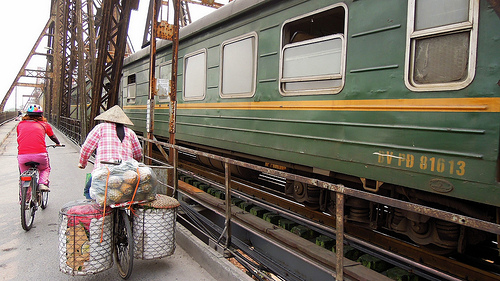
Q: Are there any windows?
A: Yes, there is a window.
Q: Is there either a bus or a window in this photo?
A: Yes, there is a window.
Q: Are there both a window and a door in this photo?
A: No, there is a window but no doors.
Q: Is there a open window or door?
A: Yes, there is an open window.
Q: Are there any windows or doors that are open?
A: Yes, the window is open.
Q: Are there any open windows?
A: Yes, there is an open window.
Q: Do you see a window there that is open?
A: Yes, there is a window that is open.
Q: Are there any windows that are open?
A: Yes, there is a window that is open.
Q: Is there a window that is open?
A: Yes, there is a window that is open.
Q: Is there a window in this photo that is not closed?
A: Yes, there is a open window.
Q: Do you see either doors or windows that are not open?
A: No, there is a window but it is open.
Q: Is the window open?
A: Yes, the window is open.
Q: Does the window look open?
A: Yes, the window is open.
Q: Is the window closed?
A: No, the window is open.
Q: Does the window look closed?
A: No, the window is open.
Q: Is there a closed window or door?
A: No, there is a window but it is open.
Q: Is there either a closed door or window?
A: No, there is a window but it is open.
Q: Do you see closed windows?
A: No, there is a window but it is open.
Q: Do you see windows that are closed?
A: No, there is a window but it is open.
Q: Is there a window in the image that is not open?
A: No, there is a window but it is open.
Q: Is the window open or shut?
A: The window is open.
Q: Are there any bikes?
A: Yes, there is a bike.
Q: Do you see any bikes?
A: Yes, there is a bike.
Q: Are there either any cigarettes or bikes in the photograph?
A: Yes, there is a bike.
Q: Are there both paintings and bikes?
A: No, there is a bike but no paintings.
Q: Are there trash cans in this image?
A: No, there are no trash cans.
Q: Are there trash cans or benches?
A: No, there are no trash cans or benches.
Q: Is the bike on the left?
A: Yes, the bike is on the left of the image.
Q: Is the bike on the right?
A: No, the bike is on the left of the image.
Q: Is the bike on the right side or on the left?
A: The bike is on the left of the image.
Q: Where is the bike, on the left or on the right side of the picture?
A: The bike is on the left of the image.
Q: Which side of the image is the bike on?
A: The bike is on the left of the image.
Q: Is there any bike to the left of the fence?
A: Yes, there is a bike to the left of the fence.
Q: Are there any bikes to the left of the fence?
A: Yes, there is a bike to the left of the fence.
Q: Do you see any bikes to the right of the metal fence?
A: No, the bike is to the left of the fence.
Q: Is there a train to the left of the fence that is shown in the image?
A: No, there is a bike to the left of the fence.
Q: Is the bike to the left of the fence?
A: Yes, the bike is to the left of the fence.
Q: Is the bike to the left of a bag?
A: No, the bike is to the left of the fence.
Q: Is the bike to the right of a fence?
A: No, the bike is to the left of a fence.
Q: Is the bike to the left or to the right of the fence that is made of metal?
A: The bike is to the left of the fence.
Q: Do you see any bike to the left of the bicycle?
A: Yes, there is a bike to the left of the bicycle.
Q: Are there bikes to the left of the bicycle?
A: Yes, there is a bike to the left of the bicycle.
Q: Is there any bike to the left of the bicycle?
A: Yes, there is a bike to the left of the bicycle.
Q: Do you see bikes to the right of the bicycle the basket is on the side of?
A: No, the bike is to the left of the bicycle.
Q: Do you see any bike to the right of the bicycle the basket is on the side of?
A: No, the bike is to the left of the bicycle.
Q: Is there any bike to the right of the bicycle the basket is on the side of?
A: No, the bike is to the left of the bicycle.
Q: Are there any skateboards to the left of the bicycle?
A: No, there is a bike to the left of the bicycle.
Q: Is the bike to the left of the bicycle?
A: Yes, the bike is to the left of the bicycle.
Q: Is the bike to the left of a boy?
A: No, the bike is to the left of the bicycle.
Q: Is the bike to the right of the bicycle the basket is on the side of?
A: No, the bike is to the left of the bicycle.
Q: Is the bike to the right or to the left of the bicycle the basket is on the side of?
A: The bike is to the left of the bicycle.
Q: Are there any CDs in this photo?
A: No, there are no cds.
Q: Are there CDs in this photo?
A: No, there are no cds.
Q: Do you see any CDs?
A: No, there are no cds.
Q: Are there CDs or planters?
A: No, there are no CDs or planters.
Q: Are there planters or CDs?
A: No, there are no CDs or planters.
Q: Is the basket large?
A: Yes, the basket is large.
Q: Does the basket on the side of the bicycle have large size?
A: Yes, the basket is large.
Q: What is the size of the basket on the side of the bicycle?
A: The basket is large.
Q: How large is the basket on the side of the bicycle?
A: The basket is large.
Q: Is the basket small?
A: No, the basket is large.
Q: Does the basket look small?
A: No, the basket is large.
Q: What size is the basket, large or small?
A: The basket is large.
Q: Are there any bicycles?
A: Yes, there is a bicycle.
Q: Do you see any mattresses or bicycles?
A: Yes, there is a bicycle.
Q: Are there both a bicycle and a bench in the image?
A: No, there is a bicycle but no benches.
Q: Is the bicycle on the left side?
A: Yes, the bicycle is on the left of the image.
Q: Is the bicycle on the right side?
A: No, the bicycle is on the left of the image.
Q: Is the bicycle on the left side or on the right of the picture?
A: The bicycle is on the left of the image.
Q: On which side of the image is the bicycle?
A: The bicycle is on the left of the image.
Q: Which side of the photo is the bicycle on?
A: The bicycle is on the left of the image.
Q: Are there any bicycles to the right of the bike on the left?
A: Yes, there is a bicycle to the right of the bike.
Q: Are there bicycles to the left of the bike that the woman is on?
A: No, the bicycle is to the right of the bike.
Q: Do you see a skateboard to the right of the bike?
A: No, there is a bicycle to the right of the bike.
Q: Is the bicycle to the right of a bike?
A: Yes, the bicycle is to the right of a bike.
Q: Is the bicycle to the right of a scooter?
A: No, the bicycle is to the right of a bike.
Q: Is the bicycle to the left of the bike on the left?
A: No, the bicycle is to the right of the bike.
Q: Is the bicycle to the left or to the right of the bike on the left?
A: The bicycle is to the right of the bike.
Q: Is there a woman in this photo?
A: Yes, there is a woman.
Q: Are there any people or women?
A: Yes, there is a woman.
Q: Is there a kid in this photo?
A: No, there are no children.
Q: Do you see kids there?
A: No, there are no kids.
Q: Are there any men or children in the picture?
A: No, there are no children or men.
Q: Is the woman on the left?
A: Yes, the woman is on the left of the image.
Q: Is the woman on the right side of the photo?
A: No, the woman is on the left of the image.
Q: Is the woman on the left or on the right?
A: The woman is on the left of the image.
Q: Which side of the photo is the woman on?
A: The woman is on the left of the image.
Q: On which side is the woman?
A: The woman is on the left of the image.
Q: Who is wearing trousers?
A: The woman is wearing trousers.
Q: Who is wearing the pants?
A: The woman is wearing trousers.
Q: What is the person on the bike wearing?
A: The woman is wearing trousers.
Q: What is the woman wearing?
A: The woman is wearing trousers.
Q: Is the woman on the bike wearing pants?
A: Yes, the woman is wearing pants.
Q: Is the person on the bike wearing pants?
A: Yes, the woman is wearing pants.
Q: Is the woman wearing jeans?
A: No, the woman is wearing pants.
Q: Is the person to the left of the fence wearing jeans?
A: No, the woman is wearing pants.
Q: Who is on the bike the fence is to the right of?
A: The woman is on the bike.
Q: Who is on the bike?
A: The woman is on the bike.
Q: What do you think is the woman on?
A: The woman is on the bike.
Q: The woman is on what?
A: The woman is on the bike.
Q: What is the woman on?
A: The woman is on the bike.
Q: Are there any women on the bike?
A: Yes, there is a woman on the bike.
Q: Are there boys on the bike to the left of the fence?
A: No, there is a woman on the bike.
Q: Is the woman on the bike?
A: Yes, the woman is on the bike.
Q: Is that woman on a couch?
A: No, the woman is on the bike.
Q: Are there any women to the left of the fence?
A: Yes, there is a woman to the left of the fence.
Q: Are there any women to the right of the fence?
A: No, the woman is to the left of the fence.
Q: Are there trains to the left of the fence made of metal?
A: No, there is a woman to the left of the fence.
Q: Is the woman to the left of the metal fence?
A: Yes, the woman is to the left of the fence.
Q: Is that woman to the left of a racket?
A: No, the woman is to the left of the fence.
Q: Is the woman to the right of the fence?
A: No, the woman is to the left of the fence.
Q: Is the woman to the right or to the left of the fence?
A: The woman is to the left of the fence.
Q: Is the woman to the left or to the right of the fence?
A: The woman is to the left of the fence.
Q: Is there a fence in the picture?
A: Yes, there is a fence.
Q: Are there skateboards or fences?
A: Yes, there is a fence.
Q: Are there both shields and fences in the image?
A: No, there is a fence but no shields.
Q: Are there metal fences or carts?
A: Yes, there is a metal fence.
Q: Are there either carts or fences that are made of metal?
A: Yes, the fence is made of metal.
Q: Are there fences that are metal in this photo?
A: Yes, there is a metal fence.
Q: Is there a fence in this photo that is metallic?
A: Yes, there is a fence that is metallic.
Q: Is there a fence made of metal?
A: Yes, there is a fence that is made of metal.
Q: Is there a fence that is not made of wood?
A: Yes, there is a fence that is made of metal.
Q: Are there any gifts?
A: No, there are no gifts.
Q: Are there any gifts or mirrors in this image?
A: No, there are no gifts or mirrors.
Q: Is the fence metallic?
A: Yes, the fence is metallic.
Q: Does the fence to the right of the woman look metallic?
A: Yes, the fence is metallic.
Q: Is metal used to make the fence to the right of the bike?
A: Yes, the fence is made of metal.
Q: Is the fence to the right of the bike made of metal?
A: Yes, the fence is made of metal.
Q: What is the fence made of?
A: The fence is made of metal.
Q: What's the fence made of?
A: The fence is made of metal.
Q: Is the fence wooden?
A: No, the fence is metallic.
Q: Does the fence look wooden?
A: No, the fence is metallic.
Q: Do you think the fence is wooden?
A: No, the fence is metallic.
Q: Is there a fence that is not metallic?
A: No, there is a fence but it is metallic.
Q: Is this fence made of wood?
A: No, the fence is made of metal.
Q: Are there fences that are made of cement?
A: No, there is a fence but it is made of metal.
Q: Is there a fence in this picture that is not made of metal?
A: No, there is a fence but it is made of metal.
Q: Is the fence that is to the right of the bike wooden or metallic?
A: The fence is metallic.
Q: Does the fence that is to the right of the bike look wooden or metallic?
A: The fence is metallic.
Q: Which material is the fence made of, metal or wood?
A: The fence is made of metal.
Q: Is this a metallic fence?
A: Yes, this is a metallic fence.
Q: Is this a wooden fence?
A: No, this is a metallic fence.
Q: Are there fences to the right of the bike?
A: Yes, there is a fence to the right of the bike.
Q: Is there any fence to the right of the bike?
A: Yes, there is a fence to the right of the bike.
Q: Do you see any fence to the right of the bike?
A: Yes, there is a fence to the right of the bike.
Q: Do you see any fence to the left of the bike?
A: No, the fence is to the right of the bike.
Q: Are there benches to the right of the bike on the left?
A: No, there is a fence to the right of the bike.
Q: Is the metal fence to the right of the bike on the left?
A: Yes, the fence is to the right of the bike.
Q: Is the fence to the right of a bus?
A: No, the fence is to the right of the bike.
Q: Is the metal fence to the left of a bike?
A: No, the fence is to the right of a bike.